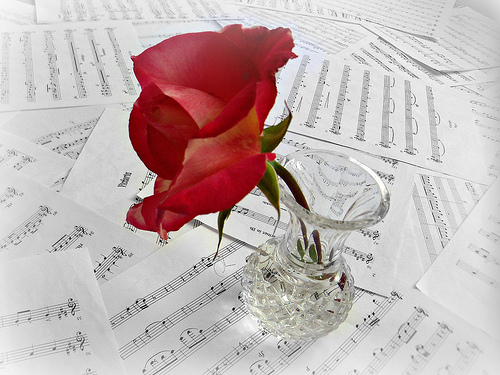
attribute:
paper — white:
[99, 222, 499, 374]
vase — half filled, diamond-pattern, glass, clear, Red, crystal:
[237, 147, 390, 341]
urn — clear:
[242, 141, 392, 338]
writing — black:
[301, 58, 488, 202]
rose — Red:
[122, 20, 392, 344]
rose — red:
[107, 22, 327, 281]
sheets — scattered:
[17, 19, 199, 360]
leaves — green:
[214, 98, 295, 260]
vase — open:
[231, 137, 423, 354]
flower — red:
[107, 11, 299, 241]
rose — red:
[88, 20, 341, 211]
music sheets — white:
[10, 7, 479, 373]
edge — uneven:
[227, 18, 295, 105]